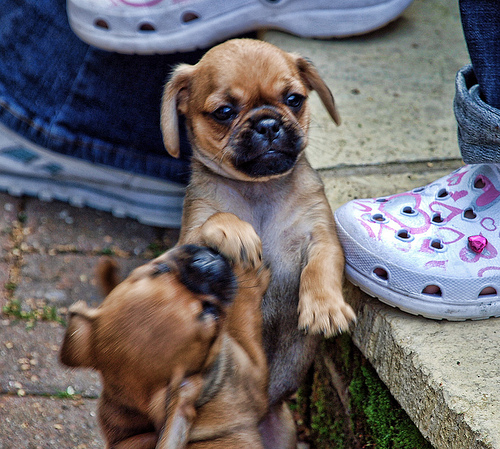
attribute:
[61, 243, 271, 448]
puppy — fighting, brown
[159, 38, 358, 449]
puppy — fighting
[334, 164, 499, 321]
croc — white, shoe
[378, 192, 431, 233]
heart — pink, purple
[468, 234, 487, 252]
heart — pink, metallic, small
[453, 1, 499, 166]
pant-leg — denim, worn, blue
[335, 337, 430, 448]
moss — green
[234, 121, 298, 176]
muzzle — black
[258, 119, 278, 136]
nose — black, leathery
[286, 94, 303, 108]
eye — brown, black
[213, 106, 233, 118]
eye — brown, black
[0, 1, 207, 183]
pant-leg — blue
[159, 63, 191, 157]
ear — long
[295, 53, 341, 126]
ear — long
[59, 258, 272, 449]
fur — brown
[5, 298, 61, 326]
plants — green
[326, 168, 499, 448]
slab — concrete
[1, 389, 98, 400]
line — on ground